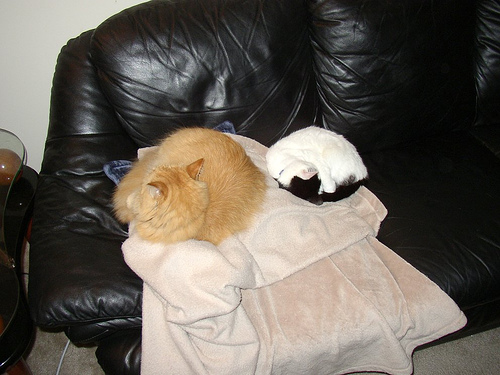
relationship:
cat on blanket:
[111, 126, 267, 244] [282, 241, 363, 290]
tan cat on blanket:
[210, 158, 245, 194] [282, 241, 363, 290]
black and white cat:
[300, 185, 314, 199] [264, 123, 369, 204]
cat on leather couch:
[111, 126, 267, 244] [30, 2, 497, 347]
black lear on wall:
[126, 40, 180, 67] [6, 20, 33, 83]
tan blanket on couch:
[210, 158, 245, 194] [30, 2, 497, 347]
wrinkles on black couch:
[316, 70, 338, 113] [30, 2, 497, 347]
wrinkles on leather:
[316, 70, 338, 113] [367, 43, 423, 99]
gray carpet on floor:
[438, 348, 480, 366] [424, 357, 445, 374]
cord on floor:
[56, 347, 71, 370] [424, 357, 445, 374]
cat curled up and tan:
[111, 126, 267, 244] [210, 158, 245, 194]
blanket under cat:
[282, 241, 363, 290] [111, 126, 267, 244]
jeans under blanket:
[109, 161, 125, 180] [282, 241, 363, 290]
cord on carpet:
[56, 347, 71, 370] [70, 354, 93, 374]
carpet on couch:
[70, 354, 93, 374] [30, 2, 497, 347]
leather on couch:
[367, 43, 423, 99] [30, 2, 497, 347]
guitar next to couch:
[1, 126, 29, 276] [30, 2, 497, 347]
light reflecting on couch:
[129, 57, 155, 78] [30, 2, 497, 347]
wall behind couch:
[6, 20, 33, 83] [30, 2, 497, 347]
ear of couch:
[183, 160, 210, 177] [30, 2, 497, 347]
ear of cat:
[183, 160, 210, 177] [264, 123, 369, 204]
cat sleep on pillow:
[264, 123, 369, 204] [143, 244, 225, 310]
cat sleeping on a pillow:
[111, 126, 267, 244] [143, 244, 225, 310]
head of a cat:
[142, 161, 204, 223] [264, 123, 369, 204]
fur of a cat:
[216, 155, 233, 175] [264, 123, 369, 204]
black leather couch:
[300, 185, 314, 199] [30, 2, 497, 347]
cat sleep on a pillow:
[111, 126, 267, 244] [143, 244, 225, 310]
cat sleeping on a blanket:
[111, 126, 267, 244] [282, 241, 363, 290]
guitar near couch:
[1, 126, 29, 276] [30, 2, 497, 347]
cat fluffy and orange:
[111, 123, 265, 240] [216, 166, 240, 195]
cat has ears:
[111, 123, 265, 240] [140, 158, 205, 194]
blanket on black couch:
[282, 241, 363, 290] [30, 2, 497, 347]